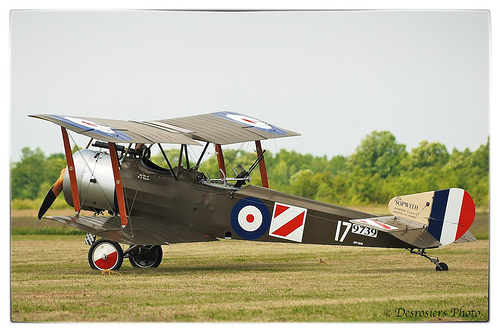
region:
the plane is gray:
[159, 192, 197, 227]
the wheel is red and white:
[91, 240, 123, 272]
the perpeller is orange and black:
[39, 171, 71, 214]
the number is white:
[328, 211, 349, 247]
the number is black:
[350, 218, 380, 243]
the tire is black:
[86, 241, 98, 263]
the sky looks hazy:
[326, 36, 388, 91]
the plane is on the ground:
[42, 101, 179, 322]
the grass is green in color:
[221, 259, 263, 291]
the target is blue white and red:
[228, 193, 273, 243]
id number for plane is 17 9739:
[327, 208, 394, 266]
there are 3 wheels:
[80, 225, 465, 288]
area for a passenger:
[191, 148, 260, 203]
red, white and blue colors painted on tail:
[384, 175, 474, 251]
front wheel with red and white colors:
[83, 236, 123, 275]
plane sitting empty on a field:
[22, 84, 482, 294]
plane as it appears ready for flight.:
[22, 76, 483, 298]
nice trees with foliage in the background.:
[304, 115, 481, 180]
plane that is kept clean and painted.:
[21, 85, 481, 290]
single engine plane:
[25, 123, 136, 227]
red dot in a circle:
[231, 202, 264, 238]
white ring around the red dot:
[237, 207, 275, 241]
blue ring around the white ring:
[233, 200, 273, 234]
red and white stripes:
[281, 204, 312, 235]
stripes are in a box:
[266, 197, 305, 239]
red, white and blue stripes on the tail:
[427, 184, 464, 230]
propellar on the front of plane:
[37, 154, 74, 199]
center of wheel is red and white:
[89, 246, 118, 266]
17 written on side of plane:
[330, 219, 349, 264]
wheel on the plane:
[418, 266, 452, 274]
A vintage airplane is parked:
[21, 66, 481, 301]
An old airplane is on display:
[23, 55, 480, 307]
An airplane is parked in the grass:
[20, 70, 481, 286]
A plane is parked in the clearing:
[20, 70, 480, 287]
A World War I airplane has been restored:
[26, 65, 476, 280]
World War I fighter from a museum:
[26, 71, 476, 281]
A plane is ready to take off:
[25, 71, 482, 281]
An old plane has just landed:
[20, 56, 480, 286]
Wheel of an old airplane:
[86, 235, 117, 270]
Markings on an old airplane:
[230, 195, 308, 240]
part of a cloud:
[293, 68, 325, 92]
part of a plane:
[311, 226, 323, 241]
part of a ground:
[221, 282, 251, 319]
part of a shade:
[252, 248, 276, 281]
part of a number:
[328, 211, 355, 241]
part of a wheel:
[144, 250, 156, 267]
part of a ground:
[230, 262, 264, 307]